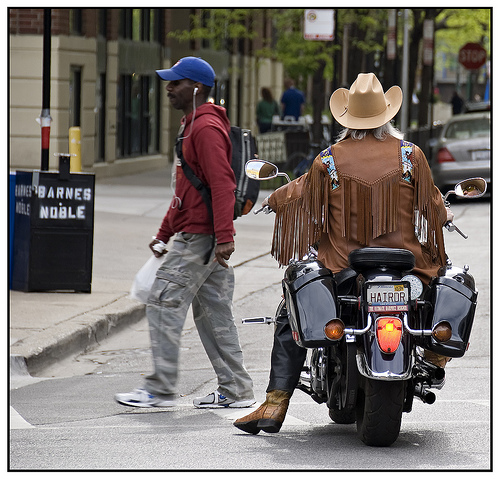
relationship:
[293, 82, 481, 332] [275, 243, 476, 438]
man riding motorcycle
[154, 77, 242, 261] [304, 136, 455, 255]
man wearing jacket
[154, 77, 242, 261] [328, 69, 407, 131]
man wearing hat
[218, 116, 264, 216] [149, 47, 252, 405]
backpack on man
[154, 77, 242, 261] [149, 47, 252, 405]
man with hat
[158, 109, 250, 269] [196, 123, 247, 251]
sweater has sleeves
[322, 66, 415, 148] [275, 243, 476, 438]
woman riding motorcycle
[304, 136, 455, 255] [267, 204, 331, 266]
jacket has tassels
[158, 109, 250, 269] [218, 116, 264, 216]
sweatshirt with backpack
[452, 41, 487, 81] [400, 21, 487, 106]
sign at intersection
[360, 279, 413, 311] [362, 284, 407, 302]
plate says hairdr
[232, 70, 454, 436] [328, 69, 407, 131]
man wearing hat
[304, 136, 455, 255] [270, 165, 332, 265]
jacket has fringe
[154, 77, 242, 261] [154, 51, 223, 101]
man wearing hat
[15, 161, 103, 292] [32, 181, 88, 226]
box with barnes and noble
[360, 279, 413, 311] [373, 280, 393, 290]
plate says illinois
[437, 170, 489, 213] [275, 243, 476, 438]
mirror on motorcycle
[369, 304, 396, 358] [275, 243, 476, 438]
light on motorcycle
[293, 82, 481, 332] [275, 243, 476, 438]
cowboy on motorcycle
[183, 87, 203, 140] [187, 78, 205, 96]
buds in ears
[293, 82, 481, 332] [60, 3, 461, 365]
rider in city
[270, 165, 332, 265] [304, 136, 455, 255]
fringe on jacket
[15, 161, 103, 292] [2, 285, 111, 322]
return on street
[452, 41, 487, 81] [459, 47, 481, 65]
sign says stop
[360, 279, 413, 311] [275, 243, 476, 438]
plate on motorcycle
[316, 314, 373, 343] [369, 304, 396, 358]
signals and light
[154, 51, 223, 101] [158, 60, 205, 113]
cap on head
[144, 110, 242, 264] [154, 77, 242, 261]
jacket on man